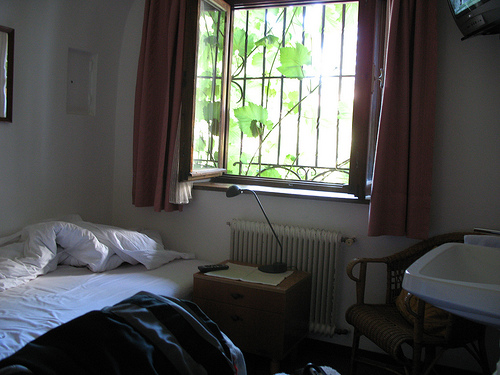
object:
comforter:
[10, 201, 180, 271]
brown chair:
[340, 223, 498, 373]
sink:
[405, 231, 499, 333]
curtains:
[126, 2, 202, 215]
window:
[179, 1, 371, 205]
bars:
[230, 3, 354, 185]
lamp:
[211, 176, 330, 313]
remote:
[191, 250, 233, 275]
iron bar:
[186, 8, 404, 223]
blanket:
[3, 292, 235, 373]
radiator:
[225, 214, 352, 332]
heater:
[230, 222, 349, 306]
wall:
[197, 197, 220, 255]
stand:
[186, 253, 306, 367]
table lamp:
[227, 193, 288, 275]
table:
[193, 249, 323, 361]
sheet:
[9, 219, 194, 363]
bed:
[8, 222, 213, 368]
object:
[230, 179, 294, 276]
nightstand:
[190, 262, 310, 371]